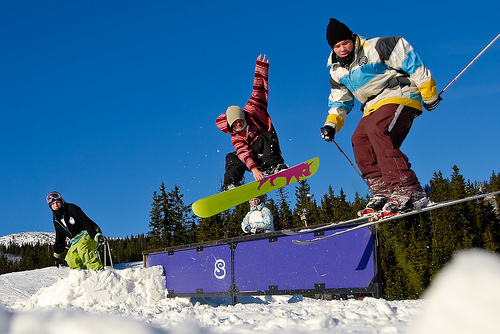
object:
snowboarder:
[194, 53, 323, 219]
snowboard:
[191, 157, 322, 222]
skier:
[44, 187, 108, 269]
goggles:
[42, 188, 63, 206]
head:
[43, 189, 64, 211]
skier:
[317, 15, 442, 214]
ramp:
[4, 261, 176, 307]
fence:
[138, 215, 383, 306]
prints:
[154, 287, 405, 331]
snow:
[0, 228, 500, 333]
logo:
[212, 254, 228, 278]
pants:
[63, 228, 105, 271]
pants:
[347, 106, 421, 199]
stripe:
[388, 104, 403, 134]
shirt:
[217, 55, 272, 171]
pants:
[221, 134, 286, 183]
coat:
[46, 201, 102, 256]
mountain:
[0, 179, 498, 331]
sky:
[1, 1, 492, 239]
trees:
[419, 161, 499, 297]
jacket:
[323, 35, 442, 132]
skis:
[280, 189, 498, 248]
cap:
[323, 18, 356, 53]